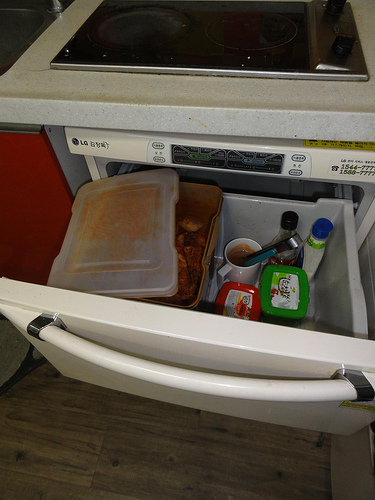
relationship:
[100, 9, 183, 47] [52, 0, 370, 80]
burner of cooktop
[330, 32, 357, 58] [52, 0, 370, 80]
knob on cooktop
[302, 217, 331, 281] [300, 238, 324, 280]
bottle of dressing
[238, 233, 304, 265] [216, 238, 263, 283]
tongs sticking out of mug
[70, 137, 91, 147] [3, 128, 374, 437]
lg on fridge